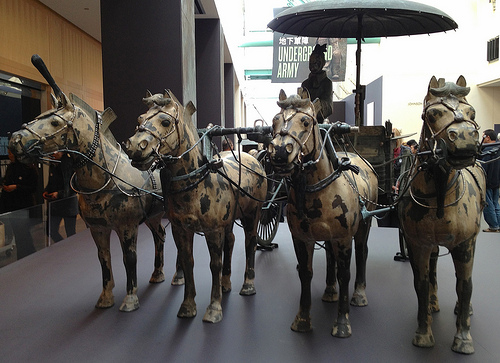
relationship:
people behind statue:
[396, 130, 499, 201] [419, 83, 494, 346]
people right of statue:
[396, 130, 499, 201] [419, 83, 494, 346]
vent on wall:
[479, 35, 499, 57] [424, 28, 499, 156]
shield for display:
[0, 197, 82, 242] [33, 104, 499, 351]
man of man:
[302, 47, 328, 104] [302, 47, 328, 104]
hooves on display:
[95, 272, 474, 362] [33, 104, 499, 351]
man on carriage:
[302, 47, 328, 104] [229, 120, 391, 214]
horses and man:
[44, 87, 499, 331] [302, 47, 328, 104]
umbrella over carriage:
[273, 8, 459, 36] [229, 120, 391, 214]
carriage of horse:
[229, 120, 391, 214] [33, 111, 183, 277]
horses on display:
[44, 87, 499, 331] [33, 104, 499, 351]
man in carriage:
[302, 47, 328, 104] [229, 120, 391, 214]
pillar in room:
[103, 3, 195, 151] [6, 3, 484, 285]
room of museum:
[6, 3, 484, 285] [6, 3, 496, 323]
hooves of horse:
[95, 272, 474, 362] [33, 111, 183, 277]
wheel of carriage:
[236, 185, 293, 253] [229, 120, 391, 214]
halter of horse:
[29, 54, 77, 106] [33, 111, 183, 277]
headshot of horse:
[16, 88, 119, 200] [33, 111, 183, 277]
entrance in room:
[5, 76, 54, 258] [6, 3, 484, 285]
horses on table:
[44, 87, 499, 331] [37, 225, 473, 362]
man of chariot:
[302, 47, 328, 104] [259, 119, 379, 201]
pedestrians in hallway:
[0, 150, 80, 233] [14, 66, 104, 223]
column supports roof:
[104, 2, 200, 171] [39, 3, 499, 114]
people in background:
[396, 130, 499, 201] [12, 13, 464, 200]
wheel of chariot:
[236, 185, 293, 253] [259, 119, 379, 201]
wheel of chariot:
[382, 185, 416, 253] [259, 119, 379, 201]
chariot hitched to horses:
[259, 119, 379, 201] [44, 87, 499, 331]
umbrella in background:
[273, 8, 459, 36] [12, 13, 464, 200]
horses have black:
[44, 87, 499, 331] [197, 191, 212, 213]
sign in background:
[274, 25, 356, 80] [12, 13, 464, 200]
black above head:
[269, 6, 461, 40] [423, 80, 480, 181]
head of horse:
[423, 80, 480, 181] [405, 84, 499, 287]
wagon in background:
[286, 95, 419, 232] [12, 13, 464, 200]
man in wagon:
[302, 47, 328, 104] [273, 107, 406, 217]